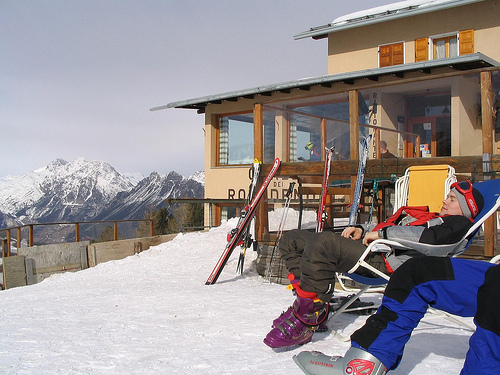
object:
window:
[429, 31, 460, 60]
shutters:
[457, 29, 477, 57]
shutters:
[414, 36, 429, 62]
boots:
[288, 347, 398, 375]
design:
[344, 358, 379, 374]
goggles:
[449, 179, 479, 218]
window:
[212, 110, 278, 170]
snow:
[328, 0, 447, 25]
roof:
[290, 1, 500, 42]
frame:
[248, 154, 497, 288]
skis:
[205, 157, 282, 286]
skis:
[313, 145, 333, 239]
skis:
[345, 134, 373, 239]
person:
[287, 256, 500, 374]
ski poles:
[364, 179, 380, 223]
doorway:
[402, 88, 456, 159]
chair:
[313, 176, 500, 332]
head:
[437, 181, 485, 217]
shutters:
[380, 43, 403, 68]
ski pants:
[346, 245, 499, 372]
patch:
[383, 252, 457, 304]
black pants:
[278, 228, 389, 295]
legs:
[295, 230, 389, 306]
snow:
[0, 202, 500, 375]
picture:
[0, 0, 497, 375]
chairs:
[391, 164, 460, 216]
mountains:
[79, 169, 209, 240]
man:
[261, 178, 486, 350]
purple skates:
[262, 292, 344, 354]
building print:
[226, 181, 299, 200]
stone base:
[0, 230, 187, 294]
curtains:
[218, 115, 229, 166]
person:
[297, 142, 321, 162]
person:
[374, 139, 398, 159]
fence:
[0, 216, 158, 258]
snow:
[0, 157, 127, 212]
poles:
[263, 182, 296, 283]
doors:
[405, 116, 437, 159]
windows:
[285, 97, 373, 162]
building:
[149, 0, 499, 259]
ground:
[0, 219, 499, 374]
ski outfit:
[276, 204, 472, 303]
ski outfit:
[349, 256, 499, 373]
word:
[227, 188, 236, 199]